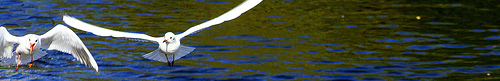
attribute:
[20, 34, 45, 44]
head — white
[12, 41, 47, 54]
beak — opened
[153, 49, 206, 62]
feathers — white, tail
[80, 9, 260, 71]
bird — larger, winged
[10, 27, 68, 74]
bird — white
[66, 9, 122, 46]
wing — larger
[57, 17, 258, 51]
wings — outstrectched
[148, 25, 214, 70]
head — turned